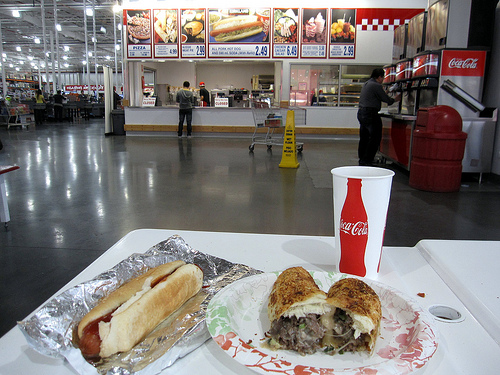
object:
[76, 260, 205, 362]
hot dog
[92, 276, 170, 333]
ketchup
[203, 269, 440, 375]
plate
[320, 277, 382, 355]
food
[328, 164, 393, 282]
cup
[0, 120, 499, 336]
floor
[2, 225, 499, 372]
table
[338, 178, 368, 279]
bottle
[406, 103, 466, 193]
trash can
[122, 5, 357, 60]
menu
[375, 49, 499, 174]
coke machine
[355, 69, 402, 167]
man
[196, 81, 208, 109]
people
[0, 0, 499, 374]
store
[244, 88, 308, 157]
buggy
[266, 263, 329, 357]
sandwich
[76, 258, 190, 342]
bun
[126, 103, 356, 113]
counter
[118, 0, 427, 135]
wall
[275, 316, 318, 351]
meat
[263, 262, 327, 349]
bread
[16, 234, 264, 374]
aluminum foil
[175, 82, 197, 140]
person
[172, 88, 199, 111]
shirt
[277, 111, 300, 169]
caution cone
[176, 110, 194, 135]
jeans